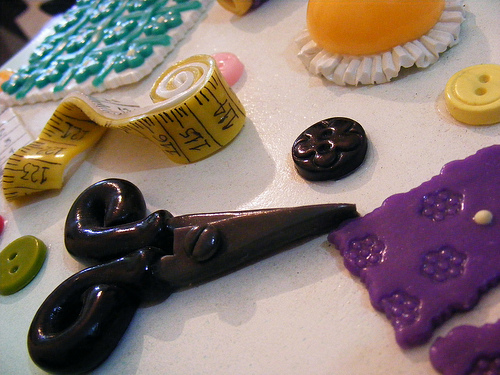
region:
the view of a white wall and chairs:
[242, 299, 261, 311]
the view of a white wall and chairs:
[285, 297, 312, 356]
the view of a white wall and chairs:
[280, 285, 305, 363]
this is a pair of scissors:
[35, 175, 347, 363]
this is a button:
[289, 97, 372, 179]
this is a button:
[0, 237, 45, 298]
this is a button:
[447, 52, 494, 144]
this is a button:
[211, 42, 244, 89]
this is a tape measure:
[0, 46, 244, 228]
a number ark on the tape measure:
[208, 97, 250, 143]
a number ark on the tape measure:
[169, 120, 221, 152]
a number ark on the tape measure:
[146, 130, 180, 168]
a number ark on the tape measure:
[10, 155, 59, 189]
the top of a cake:
[1, 6, 493, 373]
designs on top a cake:
[3, 6, 495, 371]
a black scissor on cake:
[14, 164, 372, 373]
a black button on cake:
[278, 108, 375, 192]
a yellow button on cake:
[433, 57, 498, 133]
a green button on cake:
[1, 226, 53, 306]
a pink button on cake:
[208, 46, 248, 88]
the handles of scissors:
[20, 159, 165, 369]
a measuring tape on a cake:
[1, 51, 247, 201]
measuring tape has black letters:
[1, 50, 253, 195]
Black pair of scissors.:
[27, 178, 357, 373]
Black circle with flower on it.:
[289, 116, 369, 181]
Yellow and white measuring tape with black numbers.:
[3, 52, 248, 194]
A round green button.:
[0, 237, 47, 295]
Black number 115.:
[179, 125, 209, 154]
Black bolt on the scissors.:
[182, 224, 218, 262]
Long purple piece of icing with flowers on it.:
[326, 144, 498, 346]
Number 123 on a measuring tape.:
[17, 162, 49, 184]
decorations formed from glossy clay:
[7, 6, 489, 365]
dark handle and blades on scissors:
[24, 177, 360, 370]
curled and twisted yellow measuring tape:
[2, 53, 249, 205]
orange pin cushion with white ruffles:
[282, 5, 468, 87]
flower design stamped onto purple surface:
[327, 141, 494, 347]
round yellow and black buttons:
[280, 63, 497, 183]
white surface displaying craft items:
[7, 4, 488, 364]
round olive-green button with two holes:
[1, 235, 48, 294]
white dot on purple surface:
[459, 185, 496, 255]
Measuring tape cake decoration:
[1, 51, 248, 202]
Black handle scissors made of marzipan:
[26, 175, 356, 373]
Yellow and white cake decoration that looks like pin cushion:
[296, 0, 467, 87]